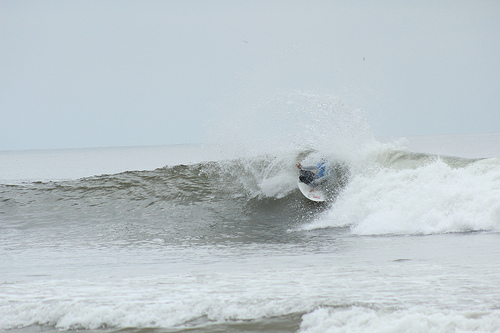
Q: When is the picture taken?
A: Daytime.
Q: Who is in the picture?
A: A surfer.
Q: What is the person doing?
A: Surfing.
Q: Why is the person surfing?
A: For fun.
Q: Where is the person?
A: On a surfboard.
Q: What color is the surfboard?
A: White.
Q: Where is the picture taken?
A: At the ocean.